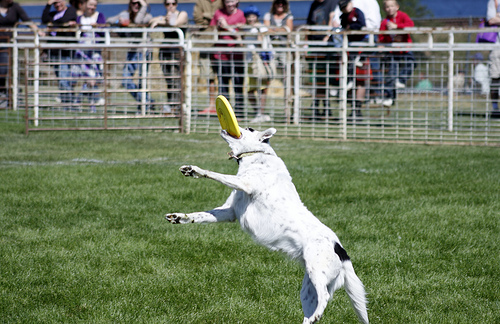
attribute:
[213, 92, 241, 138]
frisbee — yellow, green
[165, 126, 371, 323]
dog — white, jumping, black, leaping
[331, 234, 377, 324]
tail — black, white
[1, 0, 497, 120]
spectators — standing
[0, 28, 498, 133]
fence — metal, white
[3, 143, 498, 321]
grass — bright, green, short, bright green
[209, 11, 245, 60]
shirt — pink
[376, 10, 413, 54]
shirt — red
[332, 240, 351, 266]
spot — black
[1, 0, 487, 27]
roof — blue